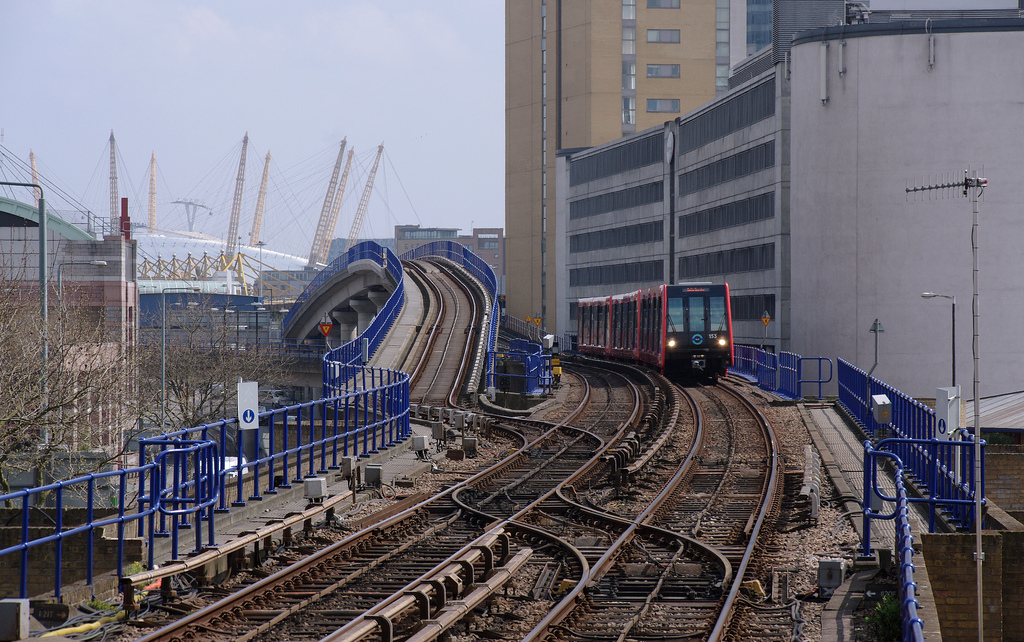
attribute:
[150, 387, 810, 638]
tracks — set , train 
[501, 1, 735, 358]
building — brown , tall 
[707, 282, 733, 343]
window — BLACK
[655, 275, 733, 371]
train — RED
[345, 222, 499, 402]
track — train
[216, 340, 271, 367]
leaves — green 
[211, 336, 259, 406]
tree — one